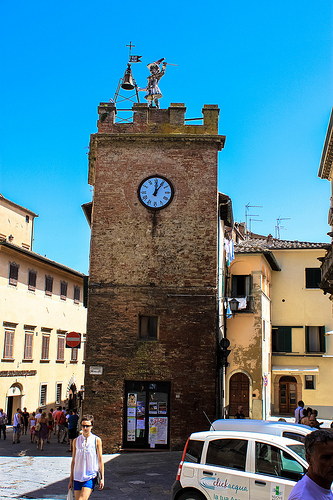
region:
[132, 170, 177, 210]
rounc clock on tall tower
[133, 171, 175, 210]
round clock reading 5 minutes after 12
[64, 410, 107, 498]
woman walking away from tower wearing a white shirt and blue shorts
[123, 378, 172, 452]
double doors of tower covered in flyers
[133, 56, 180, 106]
statue of bell ringer on top of tower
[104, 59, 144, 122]
bell on top of tower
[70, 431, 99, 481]
white shirt of the woman in white shirt and blue shorts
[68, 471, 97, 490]
blue shorts of the woman with white shirt and blue shorts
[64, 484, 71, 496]
bag the woman in the white shirt and blue shorts is carrying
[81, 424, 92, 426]
sunglasses the woman with white shirt and blue shorts is wearing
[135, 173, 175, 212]
Black and white clock on a tower.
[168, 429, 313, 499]
A white suv with writing on the door.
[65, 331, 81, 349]
A red circle with a white dash through the middle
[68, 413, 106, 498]
A woman walking in a long white shirt and blue shorts.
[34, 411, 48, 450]
A woman with her hair up walking away in a dress.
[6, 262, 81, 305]
Five windows on the top story of a tan building.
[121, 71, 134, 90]
Brass bell on the top of a building.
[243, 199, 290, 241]
Several antennas on the top of a roof to the right of a clock.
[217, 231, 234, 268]
Clothes hanging out windows to the right of a clock off the top story.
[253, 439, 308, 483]
Passenger side window of a white suv.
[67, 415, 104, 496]
woman wearing white shirt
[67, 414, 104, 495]
woman wearing blue shorts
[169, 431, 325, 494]
white car parked on street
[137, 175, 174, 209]
big clock on tower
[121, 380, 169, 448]
double door on tower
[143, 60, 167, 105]
statue on top of tower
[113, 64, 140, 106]
bell on top of tower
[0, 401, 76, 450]
tourists walking on cobblestone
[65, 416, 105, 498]
woman holding plastic bag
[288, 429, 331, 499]
man wearing white shirt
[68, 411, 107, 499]
Woman wearing white top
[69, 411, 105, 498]
Woman wearing blue shorts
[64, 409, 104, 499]
Woman wearing sunglasses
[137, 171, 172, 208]
Round black and white clock on building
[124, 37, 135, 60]
Cross attached to bell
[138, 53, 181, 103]
Statue on top of building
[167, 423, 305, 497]
White car is parked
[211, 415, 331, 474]
White car is parked next to white car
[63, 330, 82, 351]
Circular red and white traffic sign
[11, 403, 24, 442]
Person is walking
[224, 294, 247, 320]
people hanging their linens out of their window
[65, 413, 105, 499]
woman cutely dressed in blue jean shorts and a white flowy cotton shirt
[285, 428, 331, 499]
darker man wearing a white t-shirt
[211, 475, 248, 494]
name of a company on the car that makes people laugh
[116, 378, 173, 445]
dounle doors leading into a store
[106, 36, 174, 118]
pirate puss in boots on top of the building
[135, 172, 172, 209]
white clock rimmed with black that says 12:05 pm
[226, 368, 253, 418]
awesome arched doorway made of dark wood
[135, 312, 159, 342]
tiny square window in the brick tower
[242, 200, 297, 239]
antennas for tv stations